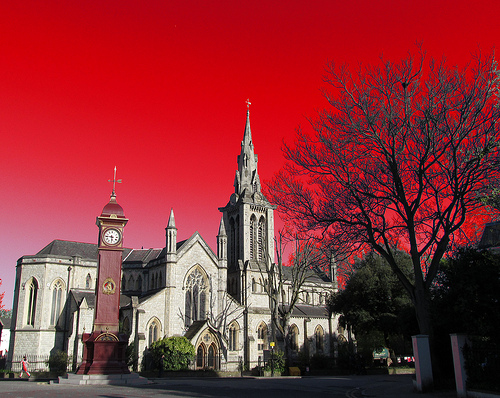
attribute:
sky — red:
[14, 35, 490, 201]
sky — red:
[0, 3, 495, 308]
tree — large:
[325, 242, 430, 375]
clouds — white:
[125, 67, 180, 118]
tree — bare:
[286, 70, 474, 252]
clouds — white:
[0, 212, 305, 315]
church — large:
[17, 102, 384, 380]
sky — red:
[29, 15, 496, 167]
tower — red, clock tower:
[94, 167, 126, 369]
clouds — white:
[7, 130, 174, 232]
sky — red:
[8, 5, 262, 82]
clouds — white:
[0, 0, 497, 309]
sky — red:
[39, 32, 217, 150]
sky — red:
[4, 1, 496, 229]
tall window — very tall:
[48, 275, 66, 335]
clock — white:
[102, 228, 119, 246]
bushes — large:
[145, 333, 194, 375]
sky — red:
[15, 15, 336, 145]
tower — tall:
[51, 176, 163, 361]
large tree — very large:
[262, 35, 498, 388]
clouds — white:
[30, 136, 246, 288]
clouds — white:
[138, 56, 230, 127]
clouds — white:
[5, 214, 50, 243]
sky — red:
[2, 3, 498, 185]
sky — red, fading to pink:
[1, 1, 498, 256]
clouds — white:
[45, 150, 95, 207]